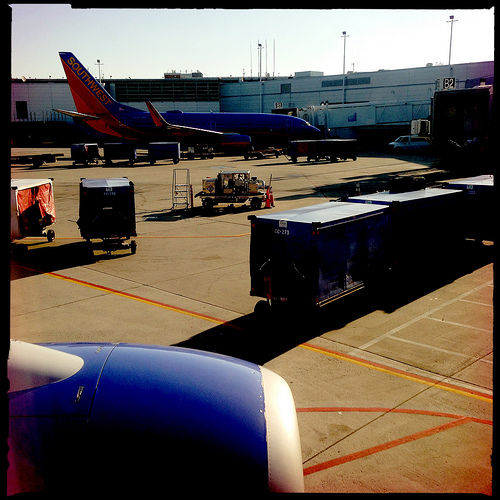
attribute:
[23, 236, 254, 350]
ground — concrere, grey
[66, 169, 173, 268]
car — carrying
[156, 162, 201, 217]
stairs — white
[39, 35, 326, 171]
plane — blue, red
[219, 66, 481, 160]
airport — white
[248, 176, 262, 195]
person — standing, working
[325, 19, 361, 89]
pole — gray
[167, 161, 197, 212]
ladder — silver, small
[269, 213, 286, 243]
sign — small, black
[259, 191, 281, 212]
cone — orange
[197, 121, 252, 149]
engine — blue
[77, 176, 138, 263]
baggage car — blue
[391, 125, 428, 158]
van — white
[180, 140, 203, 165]
wheel — black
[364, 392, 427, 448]
line — red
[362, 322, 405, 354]
line — painted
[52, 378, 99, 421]
number — 2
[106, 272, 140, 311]
line — yellow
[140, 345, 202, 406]
color — blue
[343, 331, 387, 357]
paint — white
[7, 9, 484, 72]
sky — hazy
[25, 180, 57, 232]
tarp — orange